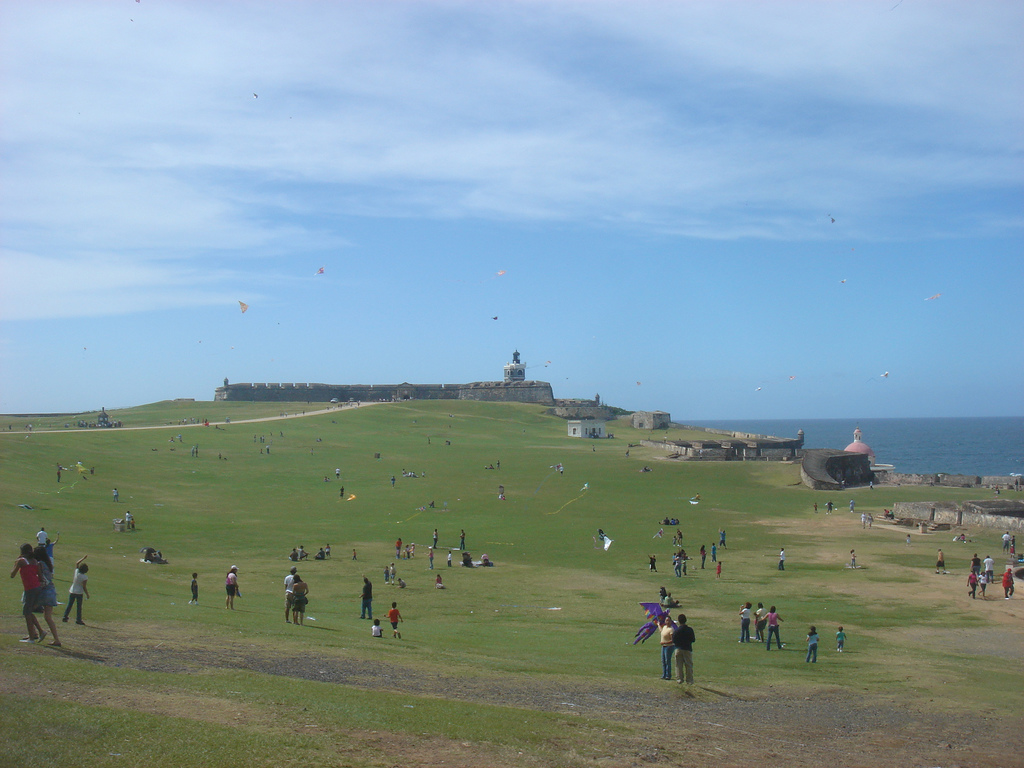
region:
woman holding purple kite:
[656, 611, 675, 679]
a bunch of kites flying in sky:
[181, 16, 946, 384]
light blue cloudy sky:
[2, 1, 1020, 422]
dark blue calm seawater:
[690, 418, 1022, 476]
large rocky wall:
[219, 376, 564, 411]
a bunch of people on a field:
[14, 410, 1021, 692]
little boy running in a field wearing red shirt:
[383, 598, 406, 641]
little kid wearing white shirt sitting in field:
[368, 613, 384, 642]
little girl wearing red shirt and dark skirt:
[8, 537, 43, 652]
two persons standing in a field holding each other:
[282, 566, 308, 639]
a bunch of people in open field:
[14, 432, 1020, 686]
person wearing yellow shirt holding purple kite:
[656, 615, 677, 683]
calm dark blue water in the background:
[669, 416, 1021, 474]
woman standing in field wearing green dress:
[290, 577, 307, 622]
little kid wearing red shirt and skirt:
[9, 542, 44, 647]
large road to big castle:
[0, 397, 380, 439]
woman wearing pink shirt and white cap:
[221, 562, 247, 611]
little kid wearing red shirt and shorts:
[384, 602, 401, 640]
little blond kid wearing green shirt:
[833, 624, 850, 654]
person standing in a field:
[797, 616, 827, 662]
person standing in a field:
[774, 543, 794, 578]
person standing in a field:
[697, 537, 714, 569]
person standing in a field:
[762, 601, 785, 652]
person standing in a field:
[749, 598, 768, 646]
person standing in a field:
[735, 591, 758, 646]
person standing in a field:
[670, 610, 705, 684]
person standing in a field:
[650, 613, 680, 672]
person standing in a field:
[356, 572, 385, 618]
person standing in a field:
[672, 612, 699, 689]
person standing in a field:
[735, 598, 755, 640]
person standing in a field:
[751, 603, 765, 642]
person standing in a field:
[386, 593, 406, 644]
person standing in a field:
[357, 569, 377, 626]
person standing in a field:
[221, 562, 247, 608]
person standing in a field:
[9, 543, 57, 641]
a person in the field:
[650, 616, 708, 694]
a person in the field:
[812, 601, 835, 679]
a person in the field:
[742, 610, 772, 636]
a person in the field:
[759, 575, 789, 662]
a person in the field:
[384, 572, 413, 642]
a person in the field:
[347, 575, 366, 632]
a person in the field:
[250, 558, 298, 607]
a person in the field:
[212, 559, 242, 618]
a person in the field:
[92, 520, 150, 571]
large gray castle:
[166, 339, 565, 420]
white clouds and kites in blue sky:
[367, 101, 415, 139]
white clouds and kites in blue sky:
[665, 19, 739, 103]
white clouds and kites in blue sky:
[722, 367, 776, 409]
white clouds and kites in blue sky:
[795, 250, 879, 305]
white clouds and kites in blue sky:
[427, 240, 511, 291]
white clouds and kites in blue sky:
[98, 200, 225, 292]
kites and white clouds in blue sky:
[49, 37, 168, 107]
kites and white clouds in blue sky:
[339, 78, 464, 192]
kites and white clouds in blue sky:
[766, 247, 868, 361]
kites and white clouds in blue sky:
[137, 130, 204, 188]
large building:
[216, 358, 555, 419]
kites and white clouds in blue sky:
[277, 72, 332, 112]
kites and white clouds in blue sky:
[330, 221, 470, 323]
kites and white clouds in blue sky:
[491, 148, 610, 253]